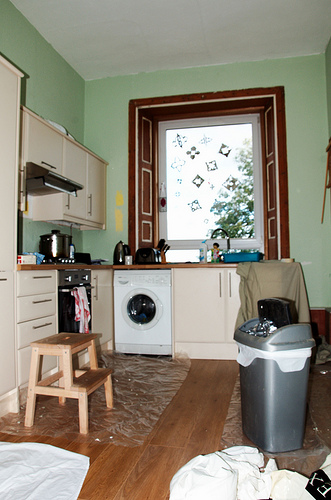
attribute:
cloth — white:
[172, 453, 222, 486]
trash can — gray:
[232, 297, 314, 450]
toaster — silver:
[134, 247, 160, 263]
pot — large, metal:
[39, 230, 73, 258]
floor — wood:
[0, 358, 238, 452]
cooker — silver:
[38, 221, 72, 266]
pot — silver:
[40, 229, 74, 259]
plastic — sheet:
[2, 348, 191, 447]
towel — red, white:
[70, 287, 95, 332]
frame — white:
[156, 121, 268, 259]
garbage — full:
[251, 287, 311, 340]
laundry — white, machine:
[113, 268, 175, 357]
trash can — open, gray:
[231, 317, 313, 451]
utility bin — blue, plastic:
[222, 250, 262, 261]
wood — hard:
[85, 373, 219, 499]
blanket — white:
[0, 439, 90, 499]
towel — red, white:
[74, 288, 92, 326]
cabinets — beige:
[73, 154, 122, 213]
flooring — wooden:
[20, 371, 311, 494]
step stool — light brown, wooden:
[21, 326, 119, 431]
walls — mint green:
[290, 65, 321, 170]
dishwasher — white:
[106, 246, 181, 363]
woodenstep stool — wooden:
[19, 311, 128, 438]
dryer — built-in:
[111, 269, 172, 357]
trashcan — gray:
[232, 290, 316, 475]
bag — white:
[231, 337, 320, 379]